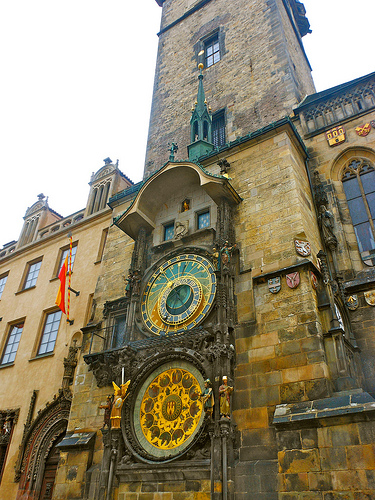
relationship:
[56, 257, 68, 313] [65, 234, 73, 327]
flag attached to pole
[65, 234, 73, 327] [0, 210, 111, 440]
pole attached to wall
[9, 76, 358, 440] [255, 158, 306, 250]
building made up of stones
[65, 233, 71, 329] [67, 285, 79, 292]
pole attached with clamps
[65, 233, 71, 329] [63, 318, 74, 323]
pole attached with clamps